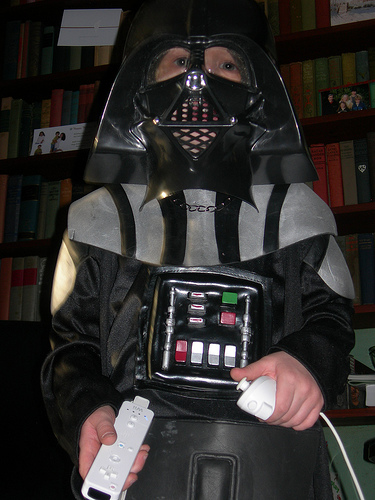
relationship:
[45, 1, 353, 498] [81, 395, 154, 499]
boy has a controller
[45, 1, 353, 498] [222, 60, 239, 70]
boy has an eye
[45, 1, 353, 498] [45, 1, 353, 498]
boy wearing a costume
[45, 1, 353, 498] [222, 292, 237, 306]
costume has buttons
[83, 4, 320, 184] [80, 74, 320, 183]
mask has a bottom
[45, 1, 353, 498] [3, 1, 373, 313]
boy in front of books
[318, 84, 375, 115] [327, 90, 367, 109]
photo of a family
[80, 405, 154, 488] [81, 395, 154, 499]
hand holding controller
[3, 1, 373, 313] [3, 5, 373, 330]
books are on shelf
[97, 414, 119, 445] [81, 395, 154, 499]
thumb on controller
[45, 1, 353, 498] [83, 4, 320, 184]
boy has on a mask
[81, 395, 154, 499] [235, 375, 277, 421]
controller for joystick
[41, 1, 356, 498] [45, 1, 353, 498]
boy in a costume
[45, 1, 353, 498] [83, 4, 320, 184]
costume has a mask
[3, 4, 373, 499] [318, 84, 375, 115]
bookshelf has a photo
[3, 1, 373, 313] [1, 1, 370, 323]
books are part of a collection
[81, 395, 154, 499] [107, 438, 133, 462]
controller has a directional pad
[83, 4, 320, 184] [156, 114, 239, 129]
mask has a chain